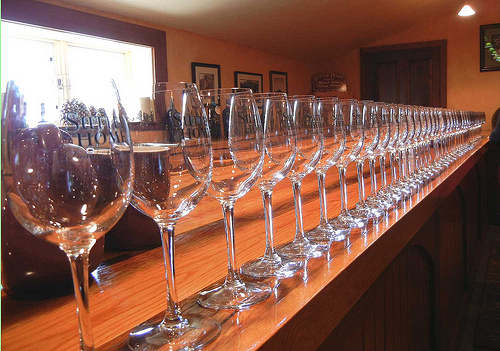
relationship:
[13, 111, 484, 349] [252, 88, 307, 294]
counter topped with glass